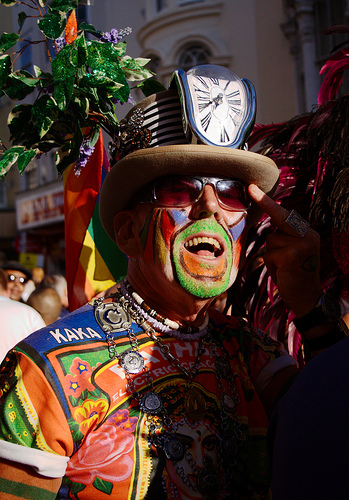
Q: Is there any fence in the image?
A: No, there are no fences.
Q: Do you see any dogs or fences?
A: No, there are no fences or dogs.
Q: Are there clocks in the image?
A: Yes, there is a clock.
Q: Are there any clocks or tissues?
A: Yes, there is a clock.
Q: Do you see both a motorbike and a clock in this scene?
A: No, there is a clock but no motorcycles.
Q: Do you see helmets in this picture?
A: No, there are no helmets.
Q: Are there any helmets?
A: No, there are no helmets.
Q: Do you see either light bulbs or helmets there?
A: No, there are no helmets or light bulbs.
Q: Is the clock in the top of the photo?
A: Yes, the clock is in the top of the image.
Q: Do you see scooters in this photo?
A: No, there are no scooters.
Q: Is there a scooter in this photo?
A: No, there are no scooters.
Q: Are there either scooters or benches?
A: No, there are no scooters or benches.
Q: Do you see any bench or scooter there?
A: No, there are no scooters or benches.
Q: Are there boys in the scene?
A: No, there are no boys.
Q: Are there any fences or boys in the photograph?
A: No, there are no boys or fences.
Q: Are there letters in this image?
A: Yes, there are letters.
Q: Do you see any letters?
A: Yes, there are letters.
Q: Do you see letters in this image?
A: Yes, there are letters.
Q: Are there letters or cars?
A: Yes, there are letters.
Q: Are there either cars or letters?
A: Yes, there are letters.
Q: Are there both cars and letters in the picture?
A: No, there are letters but no cars.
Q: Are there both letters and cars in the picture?
A: No, there are letters but no cars.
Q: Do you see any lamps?
A: No, there are no lamps.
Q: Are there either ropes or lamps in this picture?
A: No, there are no lamps or ropes.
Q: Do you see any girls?
A: No, there are no girls.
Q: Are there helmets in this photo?
A: No, there are no helmets.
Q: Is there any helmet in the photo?
A: No, there are no helmets.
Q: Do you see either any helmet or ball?
A: No, there are no helmets or balls.